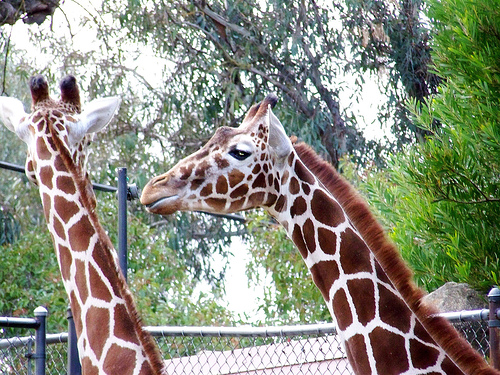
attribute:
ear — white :
[251, 98, 280, 143]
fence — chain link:
[0, 310, 497, 374]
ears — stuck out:
[1, 93, 121, 138]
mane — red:
[281, 126, 497, 371]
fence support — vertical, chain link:
[23, 303, 52, 373]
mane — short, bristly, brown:
[295, 138, 498, 365]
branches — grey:
[207, 22, 314, 89]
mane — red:
[69, 205, 157, 332]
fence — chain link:
[7, 324, 498, 373]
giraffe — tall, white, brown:
[133, 95, 484, 373]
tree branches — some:
[138, 0, 430, 146]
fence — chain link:
[0, 288, 500, 373]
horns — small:
[237, 88, 277, 126]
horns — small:
[24, 66, 82, 109]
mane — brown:
[291, 132, 456, 370]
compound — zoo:
[4, 70, 470, 361]